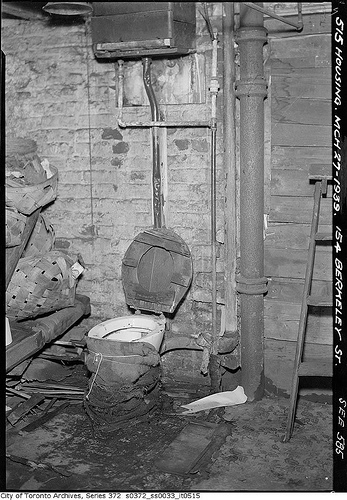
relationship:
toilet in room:
[82, 223, 193, 439] [31, 18, 328, 484]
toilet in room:
[82, 223, 193, 439] [19, 51, 328, 474]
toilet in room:
[70, 225, 181, 424] [31, 18, 328, 484]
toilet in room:
[82, 223, 193, 439] [17, 8, 319, 496]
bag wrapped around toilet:
[83, 335, 162, 424] [78, 312, 166, 428]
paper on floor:
[180, 387, 255, 417] [135, 420, 161, 461]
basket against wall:
[11, 254, 105, 320] [66, 219, 95, 260]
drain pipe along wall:
[232, 0, 271, 397] [281, 235, 294, 298]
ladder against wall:
[280, 181, 334, 443] [268, 248, 295, 293]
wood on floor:
[19, 365, 68, 418] [65, 413, 84, 452]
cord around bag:
[95, 351, 141, 364] [88, 351, 154, 415]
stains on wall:
[109, 127, 136, 167] [255, 380, 275, 402]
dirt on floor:
[78, 419, 171, 460] [113, 425, 210, 484]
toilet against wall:
[82, 223, 193, 439] [185, 292, 208, 348]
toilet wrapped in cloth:
[82, 223, 193, 439] [94, 346, 142, 406]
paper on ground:
[180, 384, 248, 416] [199, 414, 258, 464]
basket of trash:
[5, 250, 85, 325] [16, 205, 82, 389]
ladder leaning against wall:
[283, 201, 335, 434] [281, 104, 296, 201]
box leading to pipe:
[90, 3, 199, 63] [140, 55, 169, 225]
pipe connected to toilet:
[140, 55, 169, 225] [83, 229, 191, 405]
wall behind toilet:
[2, 21, 239, 355] [77, 222, 195, 412]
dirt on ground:
[73, 396, 170, 460] [8, 352, 332, 484]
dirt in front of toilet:
[73, 396, 170, 460] [82, 223, 193, 439]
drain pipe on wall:
[232, 0, 271, 397] [4, 17, 267, 369]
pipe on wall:
[140, 64, 166, 228] [2, 21, 239, 355]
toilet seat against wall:
[118, 224, 196, 324] [2, 21, 239, 355]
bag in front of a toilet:
[83, 335, 162, 424] [82, 223, 193, 439]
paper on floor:
[180, 384, 248, 416] [4, 338, 329, 486]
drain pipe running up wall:
[232, 6, 272, 389] [2, 21, 239, 355]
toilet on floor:
[82, 223, 193, 439] [4, 338, 329, 486]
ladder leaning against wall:
[280, 181, 334, 443] [2, 21, 239, 355]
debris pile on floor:
[0, 137, 106, 471] [4, 338, 329, 486]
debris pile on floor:
[12, 137, 106, 471] [8, 363, 331, 489]